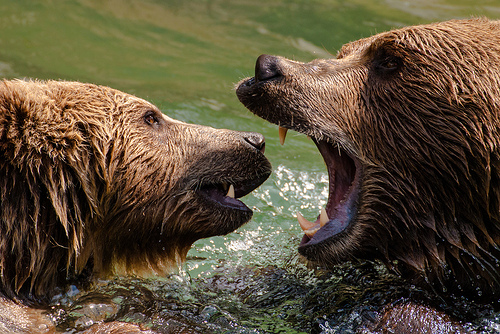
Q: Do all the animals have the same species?
A: Yes, all the animals are bears.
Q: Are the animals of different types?
A: No, all the animals are bears.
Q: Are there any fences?
A: No, there are no fences.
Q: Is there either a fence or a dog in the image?
A: No, there are no fences or dogs.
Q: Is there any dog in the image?
A: No, there are no dogs.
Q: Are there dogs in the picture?
A: No, there are no dogs.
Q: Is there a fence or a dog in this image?
A: No, there are no dogs or fences.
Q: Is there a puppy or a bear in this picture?
A: Yes, there are bears.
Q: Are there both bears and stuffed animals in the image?
A: No, there are bears but no stuffed animals.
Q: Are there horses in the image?
A: No, there are no horses.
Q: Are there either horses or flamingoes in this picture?
A: No, there are no horses or flamingoes.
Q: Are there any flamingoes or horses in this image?
A: No, there are no horses or flamingoes.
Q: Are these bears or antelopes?
A: These are bears.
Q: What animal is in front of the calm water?
A: The bears are in front of the water.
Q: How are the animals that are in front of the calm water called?
A: The animals are bears.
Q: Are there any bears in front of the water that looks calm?
A: Yes, there are bears in front of the water.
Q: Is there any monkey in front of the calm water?
A: No, there are bears in front of the water.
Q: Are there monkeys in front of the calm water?
A: No, there are bears in front of the water.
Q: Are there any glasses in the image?
A: No, there are no glasses.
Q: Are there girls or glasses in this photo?
A: No, there are no glasses or girls.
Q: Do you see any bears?
A: Yes, there is a bear.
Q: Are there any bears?
A: Yes, there is a bear.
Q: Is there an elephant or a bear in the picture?
A: Yes, there is a bear.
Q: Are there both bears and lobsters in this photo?
A: No, there is a bear but no lobsters.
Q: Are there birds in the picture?
A: No, there are no birds.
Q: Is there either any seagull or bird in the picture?
A: No, there are no birds or seagulls.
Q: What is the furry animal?
A: The animal is a bear.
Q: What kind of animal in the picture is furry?
A: The animal is a bear.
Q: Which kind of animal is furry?
A: The animal is a bear.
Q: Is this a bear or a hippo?
A: This is a bear.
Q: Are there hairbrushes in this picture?
A: No, there are no hairbrushes.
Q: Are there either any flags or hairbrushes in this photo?
A: No, there are no hairbrushes or flags.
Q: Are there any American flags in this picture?
A: No, there are no American flags.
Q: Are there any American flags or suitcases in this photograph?
A: No, there are no American flags or suitcases.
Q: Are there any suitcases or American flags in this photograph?
A: No, there are no American flags or suitcases.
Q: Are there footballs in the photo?
A: No, there are no footballs.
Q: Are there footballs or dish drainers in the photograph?
A: No, there are no footballs or dish drainers.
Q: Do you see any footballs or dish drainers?
A: No, there are no footballs or dish drainers.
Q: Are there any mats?
A: No, there are no mats.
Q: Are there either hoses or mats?
A: No, there are no mats or hoses.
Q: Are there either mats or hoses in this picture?
A: No, there are no mats or hoses.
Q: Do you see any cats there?
A: No, there are no cats.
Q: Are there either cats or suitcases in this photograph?
A: No, there are no cats or suitcases.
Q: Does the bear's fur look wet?
A: Yes, the fur is wet.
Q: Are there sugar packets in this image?
A: No, there are no sugar packets.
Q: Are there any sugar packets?
A: No, there are no sugar packets.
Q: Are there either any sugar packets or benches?
A: No, there are no sugar packets or benches.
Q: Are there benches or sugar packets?
A: No, there are no sugar packets or benches.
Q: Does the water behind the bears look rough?
A: No, the water is calm.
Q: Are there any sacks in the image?
A: No, there are no sacks.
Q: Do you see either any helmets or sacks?
A: No, there are no sacks or helmets.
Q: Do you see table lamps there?
A: No, there are no table lamps.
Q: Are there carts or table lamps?
A: No, there are no table lamps or carts.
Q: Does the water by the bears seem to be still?
A: Yes, the water is still.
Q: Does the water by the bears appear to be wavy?
A: No, the water is still.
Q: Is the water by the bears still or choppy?
A: The water is still.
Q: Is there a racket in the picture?
A: No, there are no rackets.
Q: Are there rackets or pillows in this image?
A: No, there are no rackets or pillows.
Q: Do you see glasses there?
A: No, there are no glasses.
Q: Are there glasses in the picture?
A: No, there are no glasses.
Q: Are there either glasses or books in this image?
A: No, there are no glasses or books.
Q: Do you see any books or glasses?
A: No, there are no glasses or books.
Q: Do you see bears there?
A: Yes, there is a bear.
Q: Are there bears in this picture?
A: Yes, there is a bear.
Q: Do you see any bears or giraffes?
A: Yes, there is a bear.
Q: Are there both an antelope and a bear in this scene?
A: No, there is a bear but no antelopes.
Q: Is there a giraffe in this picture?
A: No, there are no giraffes.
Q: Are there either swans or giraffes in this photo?
A: No, there are no giraffes or swans.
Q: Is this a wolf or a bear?
A: This is a bear.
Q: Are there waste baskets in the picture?
A: No, there are no waste baskets.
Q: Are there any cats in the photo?
A: No, there are no cats.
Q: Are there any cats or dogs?
A: No, there are no cats or dogs.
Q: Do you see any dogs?
A: No, there are no dogs.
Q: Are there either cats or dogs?
A: No, there are no dogs or cats.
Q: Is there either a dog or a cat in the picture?
A: No, there are no dogs or cats.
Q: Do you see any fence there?
A: No, there are no fences.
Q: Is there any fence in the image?
A: No, there are no fences.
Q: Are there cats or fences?
A: No, there are no fences or cats.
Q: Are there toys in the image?
A: No, there are no toys.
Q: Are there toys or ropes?
A: No, there are no toys or ropes.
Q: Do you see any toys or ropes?
A: No, there are no toys or ropes.